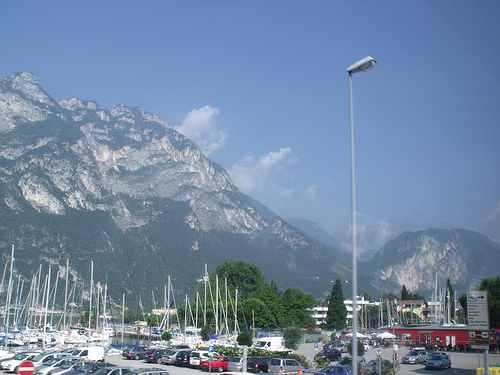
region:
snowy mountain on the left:
[43, 85, 203, 195]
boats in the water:
[21, 285, 141, 370]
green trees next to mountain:
[245, 256, 290, 311]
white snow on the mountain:
[70, 125, 174, 190]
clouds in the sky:
[256, 134, 308, 176]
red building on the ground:
[392, 313, 473, 355]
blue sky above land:
[382, 30, 457, 120]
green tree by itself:
[322, 271, 362, 328]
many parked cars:
[53, 341, 108, 373]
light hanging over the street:
[313, 38, 397, 162]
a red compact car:
[197, 349, 232, 372]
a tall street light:
[336, 46, 385, 374]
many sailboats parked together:
[1, 248, 237, 355]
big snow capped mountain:
[7, 68, 362, 310]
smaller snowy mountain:
[366, 221, 497, 317]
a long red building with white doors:
[377, 321, 498, 354]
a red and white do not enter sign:
[12, 358, 40, 373]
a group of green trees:
[179, 258, 318, 335]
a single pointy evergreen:
[323, 274, 348, 335]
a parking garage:
[305, 288, 446, 326]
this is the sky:
[189, 0, 315, 110]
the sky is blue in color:
[218, 16, 291, 73]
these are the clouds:
[186, 109, 206, 137]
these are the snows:
[153, 152, 203, 177]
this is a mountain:
[66, 97, 196, 263]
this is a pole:
[346, 75, 368, 320]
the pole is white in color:
[348, 87, 357, 151]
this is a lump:
[346, 55, 382, 82]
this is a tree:
[256, 274, 301, 305]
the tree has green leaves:
[248, 265, 258, 289]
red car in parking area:
[198, 353, 231, 369]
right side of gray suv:
[267, 355, 302, 370]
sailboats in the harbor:
[0, 316, 115, 341]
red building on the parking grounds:
[373, 320, 475, 350]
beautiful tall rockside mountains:
[3, 63, 350, 294]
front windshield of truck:
[251, 338, 266, 348]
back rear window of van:
[188, 348, 201, 358]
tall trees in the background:
[175, 253, 315, 323]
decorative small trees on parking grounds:
[161, 323, 302, 348]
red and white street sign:
[12, 360, 39, 374]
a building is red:
[388, 306, 485, 363]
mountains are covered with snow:
[6, 66, 473, 300]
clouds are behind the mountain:
[118, 69, 400, 241]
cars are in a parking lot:
[23, 349, 269, 373]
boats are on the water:
[3, 240, 265, 336]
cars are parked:
[22, 322, 257, 373]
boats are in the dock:
[7, 240, 278, 357]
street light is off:
[331, 54, 406, 358]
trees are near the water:
[210, 251, 340, 332]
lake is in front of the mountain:
[6, 283, 163, 338]